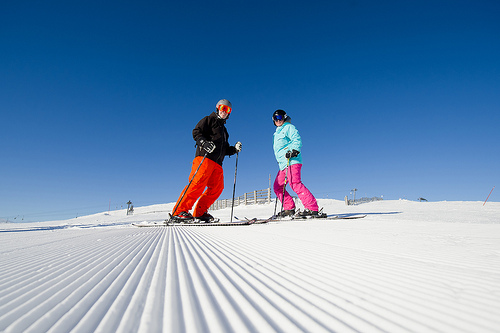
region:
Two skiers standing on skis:
[165, 96, 327, 224]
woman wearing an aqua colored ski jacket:
[272, 125, 299, 170]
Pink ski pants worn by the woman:
[271, 162, 317, 209]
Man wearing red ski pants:
[170, 155, 223, 213]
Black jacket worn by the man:
[190, 110, 233, 165]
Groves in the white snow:
[0, 223, 421, 330]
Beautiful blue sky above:
[0, 0, 495, 220]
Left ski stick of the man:
[230, 148, 240, 222]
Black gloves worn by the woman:
[285, 146, 300, 158]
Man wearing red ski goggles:
[218, 103, 233, 115]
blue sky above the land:
[36, 25, 135, 96]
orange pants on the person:
[184, 150, 237, 205]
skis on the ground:
[141, 209, 257, 236]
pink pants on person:
[255, 167, 319, 222]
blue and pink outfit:
[247, 96, 332, 211]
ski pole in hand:
[157, 150, 221, 225]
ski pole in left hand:
[221, 140, 256, 213]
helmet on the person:
[266, 93, 300, 135]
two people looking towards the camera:
[156, 89, 328, 196]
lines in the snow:
[123, 247, 255, 309]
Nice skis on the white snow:
[124, 218, 264, 229]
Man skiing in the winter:
[159, 98, 246, 230]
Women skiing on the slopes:
[252, 103, 327, 222]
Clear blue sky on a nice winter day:
[11, 60, 146, 147]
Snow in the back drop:
[326, 253, 396, 304]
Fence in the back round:
[213, 189, 279, 214]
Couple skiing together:
[164, 98, 316, 228]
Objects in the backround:
[108, 196, 143, 221]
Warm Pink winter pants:
[268, 164, 319, 219]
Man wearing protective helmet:
[203, 96, 236, 118]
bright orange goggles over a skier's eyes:
[216, 103, 231, 115]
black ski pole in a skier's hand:
[162, 138, 215, 228]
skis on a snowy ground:
[128, 216, 274, 226]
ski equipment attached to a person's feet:
[130, 209, 260, 226]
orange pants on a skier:
[169, 155, 225, 217]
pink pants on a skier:
[271, 163, 321, 211]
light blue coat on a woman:
[271, 120, 301, 171]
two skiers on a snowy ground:
[130, 98, 327, 228]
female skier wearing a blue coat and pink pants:
[265, 107, 329, 218]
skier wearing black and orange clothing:
[165, 95, 243, 225]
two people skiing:
[158, 97, 330, 227]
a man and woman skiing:
[156, 90, 359, 236]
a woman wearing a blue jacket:
[266, 103, 309, 168]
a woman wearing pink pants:
[264, 108, 335, 233]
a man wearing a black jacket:
[175, 93, 246, 234]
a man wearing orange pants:
[172, 93, 244, 223]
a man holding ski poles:
[155, 93, 245, 231]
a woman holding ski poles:
[261, 102, 340, 231]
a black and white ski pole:
[226, 142, 246, 222]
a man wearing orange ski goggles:
[212, 95, 237, 124]